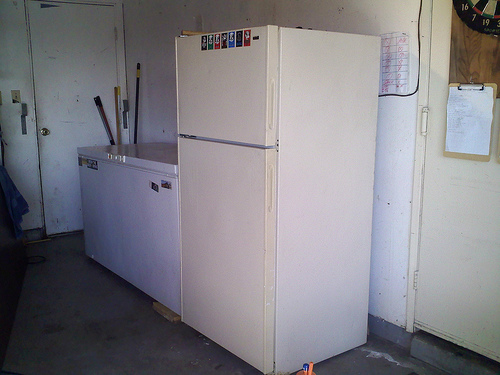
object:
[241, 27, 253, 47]
sticker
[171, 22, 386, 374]
fridge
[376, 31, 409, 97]
paper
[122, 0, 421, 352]
wall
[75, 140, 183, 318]
freezer